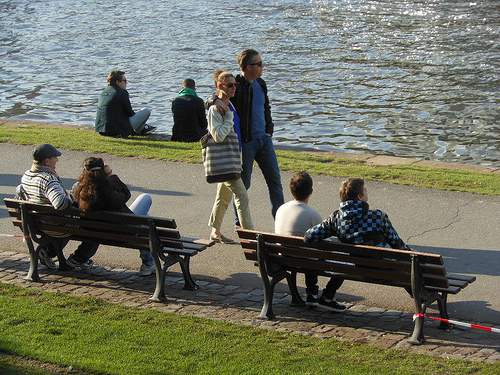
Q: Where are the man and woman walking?
A: Along the water.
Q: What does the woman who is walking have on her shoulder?
A: A bag.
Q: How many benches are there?
A: Two.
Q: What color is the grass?
A: Green.